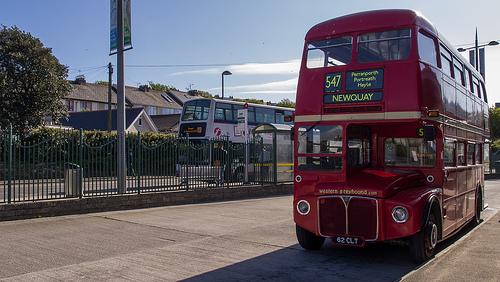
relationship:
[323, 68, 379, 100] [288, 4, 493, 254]
writing on bus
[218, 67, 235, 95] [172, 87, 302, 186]
street light behind bus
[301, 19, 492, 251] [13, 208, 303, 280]
bus on street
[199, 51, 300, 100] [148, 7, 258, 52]
clouds in sky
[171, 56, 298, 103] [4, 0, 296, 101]
clouds in sky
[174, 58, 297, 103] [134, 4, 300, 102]
could in sky